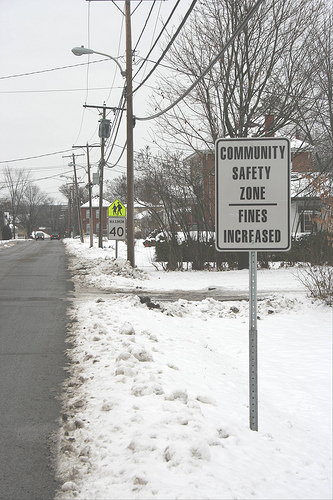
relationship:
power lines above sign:
[93, 0, 262, 64] [215, 137, 292, 253]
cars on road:
[29, 231, 63, 244] [2, 383, 56, 491]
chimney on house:
[237, 105, 297, 138] [182, 112, 332, 252]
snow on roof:
[95, 199, 101, 203] [77, 186, 123, 213]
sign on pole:
[215, 137, 292, 253] [247, 249, 259, 433]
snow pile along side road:
[88, 254, 152, 283] [2, 235, 74, 497]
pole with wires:
[100, 66, 141, 150] [74, 7, 253, 182]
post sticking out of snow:
[242, 236, 270, 430] [166, 336, 328, 480]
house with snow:
[80, 199, 111, 238] [92, 198, 99, 206]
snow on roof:
[92, 198, 99, 206] [79, 197, 114, 207]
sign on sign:
[106, 216, 125, 240] [215, 137, 292, 253]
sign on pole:
[106, 197, 125, 216] [122, 72, 141, 267]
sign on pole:
[195, 135, 293, 324] [244, 251, 260, 316]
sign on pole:
[215, 137, 292, 253] [247, 250, 257, 430]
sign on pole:
[215, 137, 292, 253] [204, 135, 295, 456]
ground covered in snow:
[0, 237, 331, 497] [63, 231, 332, 498]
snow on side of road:
[118, 300, 260, 422] [0, 228, 89, 361]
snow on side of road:
[63, 236, 121, 295] [0, 237, 82, 498]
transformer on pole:
[86, 112, 118, 131] [76, 131, 148, 248]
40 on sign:
[109, 225, 123, 237] [107, 208, 135, 248]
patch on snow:
[270, 359, 317, 418] [47, 295, 331, 498]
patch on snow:
[168, 267, 197, 283] [60, 232, 332, 296]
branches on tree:
[144, 1, 331, 175] [145, 4, 331, 237]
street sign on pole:
[104, 212, 126, 236] [110, 231, 120, 260]